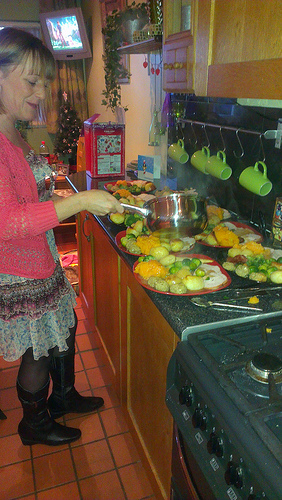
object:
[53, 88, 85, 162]
tree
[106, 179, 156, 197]
plate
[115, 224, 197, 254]
plate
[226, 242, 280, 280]
plate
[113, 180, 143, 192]
food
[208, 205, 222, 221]
food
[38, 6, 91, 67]
monitor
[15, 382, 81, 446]
boots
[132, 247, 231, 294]
food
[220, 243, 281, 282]
food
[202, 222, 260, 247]
food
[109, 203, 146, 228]
food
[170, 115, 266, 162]
hooks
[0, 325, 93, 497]
floor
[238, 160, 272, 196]
cup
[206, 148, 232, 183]
cup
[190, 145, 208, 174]
cup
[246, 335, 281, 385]
stove top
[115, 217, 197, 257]
food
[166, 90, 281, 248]
wall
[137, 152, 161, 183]
card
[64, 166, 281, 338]
countertop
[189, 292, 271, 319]
spoon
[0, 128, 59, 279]
blouse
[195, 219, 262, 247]
plate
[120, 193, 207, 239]
pot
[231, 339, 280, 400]
range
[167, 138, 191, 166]
cups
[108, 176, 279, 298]
meal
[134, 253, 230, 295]
plate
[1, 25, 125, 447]
lady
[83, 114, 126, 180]
box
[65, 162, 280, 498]
counter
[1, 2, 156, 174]
wall